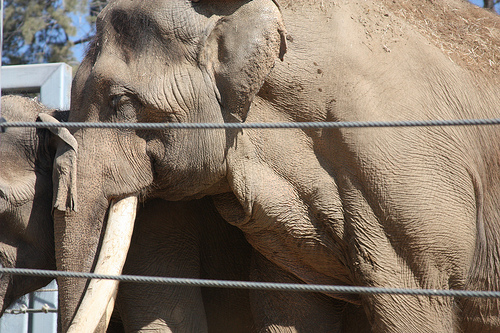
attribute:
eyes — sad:
[98, 88, 130, 115]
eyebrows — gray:
[99, 76, 128, 87]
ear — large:
[192, 6, 282, 157]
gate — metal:
[8, 30, 92, 312]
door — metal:
[0, 40, 104, 219]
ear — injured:
[209, 2, 292, 147]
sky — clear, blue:
[2, 2, 97, 64]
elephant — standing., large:
[42, 12, 493, 315]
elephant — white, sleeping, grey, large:
[36, 0, 498, 332]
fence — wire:
[1, 116, 498, 298]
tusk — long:
[69, 184, 139, 331]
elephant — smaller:
[72, 14, 499, 264]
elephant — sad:
[10, 96, 92, 241]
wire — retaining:
[1, 266, 498, 298]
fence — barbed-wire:
[3, 306, 58, 316]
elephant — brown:
[35, 0, 290, 332]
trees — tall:
[23, 10, 93, 62]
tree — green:
[7, 6, 97, 65]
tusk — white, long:
[60, 192, 139, 329]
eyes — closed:
[104, 87, 134, 109]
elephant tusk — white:
[27, 0, 286, 331]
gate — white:
[5, 61, 79, 331]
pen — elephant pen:
[0, 63, 500, 332]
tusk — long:
[51, 195, 136, 331]